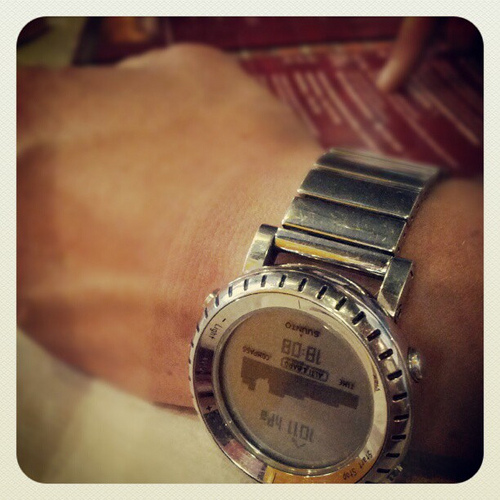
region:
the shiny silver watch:
[187, 145, 449, 483]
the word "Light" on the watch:
[207, 323, 222, 339]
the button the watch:
[408, 349, 426, 382]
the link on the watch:
[281, 195, 409, 257]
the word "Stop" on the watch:
[340, 467, 356, 483]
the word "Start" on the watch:
[355, 449, 372, 469]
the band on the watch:
[272, 144, 447, 280]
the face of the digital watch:
[215, 308, 374, 475]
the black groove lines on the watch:
[190, 272, 411, 482]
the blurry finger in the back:
[377, 17, 436, 94]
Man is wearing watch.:
[59, 120, 435, 486]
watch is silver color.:
[161, 188, 386, 448]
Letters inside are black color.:
[250, 326, 362, 437]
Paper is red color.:
[271, 47, 428, 164]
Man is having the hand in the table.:
[34, 323, 171, 460]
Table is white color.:
[47, 343, 187, 473]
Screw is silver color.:
[406, 346, 432, 388]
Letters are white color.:
[298, 55, 418, 169]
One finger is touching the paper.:
[367, 28, 437, 91]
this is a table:
[60, 412, 107, 435]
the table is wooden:
[69, 438, 144, 466]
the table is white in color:
[62, 418, 113, 444]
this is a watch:
[185, 137, 440, 487]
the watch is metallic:
[312, 191, 377, 241]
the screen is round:
[191, 255, 401, 475]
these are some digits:
[281, 334, 322, 368]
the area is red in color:
[344, 88, 409, 128]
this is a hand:
[42, 106, 218, 284]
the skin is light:
[99, 120, 189, 222]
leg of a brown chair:
[370, 51, 415, 92]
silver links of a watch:
[282, 185, 409, 245]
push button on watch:
[400, 345, 425, 380]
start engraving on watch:
[352, 450, 372, 465]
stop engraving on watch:
[341, 466, 353, 476]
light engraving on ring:
[210, 320, 220, 336]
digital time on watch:
[286, 415, 311, 442]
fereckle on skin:
[465, 225, 485, 240]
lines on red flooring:
[290, 66, 345, 123]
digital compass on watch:
[241, 346, 270, 358]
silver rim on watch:
[220, 281, 410, 456]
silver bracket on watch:
[253, 216, 280, 271]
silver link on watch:
[283, 180, 420, 253]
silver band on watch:
[282, 178, 427, 270]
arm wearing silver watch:
[191, 187, 489, 349]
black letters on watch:
[267, 321, 353, 369]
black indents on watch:
[248, 280, 313, 300]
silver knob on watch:
[410, 353, 430, 380]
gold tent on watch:
[302, 465, 382, 476]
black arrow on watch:
[288, 435, 311, 450]